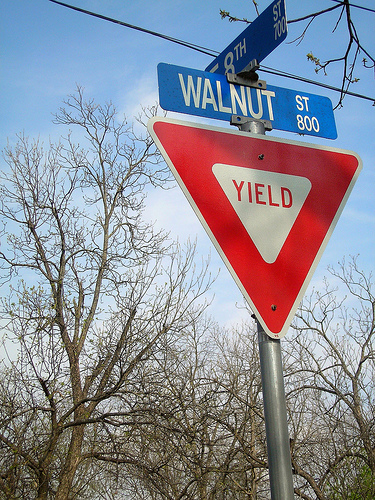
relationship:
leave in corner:
[333, 442, 351, 470] [308, 380, 341, 465]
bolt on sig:
[244, 130, 292, 170] [192, 122, 368, 305]